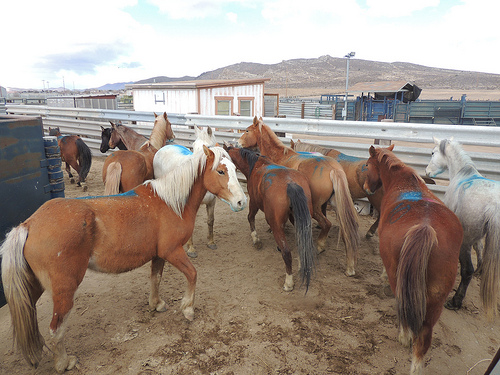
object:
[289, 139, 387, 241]
horses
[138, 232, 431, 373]
footprints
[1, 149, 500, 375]
dirt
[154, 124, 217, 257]
horse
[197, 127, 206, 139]
light hair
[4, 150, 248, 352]
horse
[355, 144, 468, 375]
horse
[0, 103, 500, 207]
fence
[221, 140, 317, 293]
horse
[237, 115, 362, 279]
horse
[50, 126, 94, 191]
horse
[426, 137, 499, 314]
horse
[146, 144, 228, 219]
mane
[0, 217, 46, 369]
tail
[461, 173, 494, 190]
paint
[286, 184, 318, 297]
tail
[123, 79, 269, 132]
building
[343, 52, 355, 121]
lamp post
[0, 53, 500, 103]
mountains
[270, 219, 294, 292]
leg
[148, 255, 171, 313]
leg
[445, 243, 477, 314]
leg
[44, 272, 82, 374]
leg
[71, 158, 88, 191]
leg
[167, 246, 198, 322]
leg